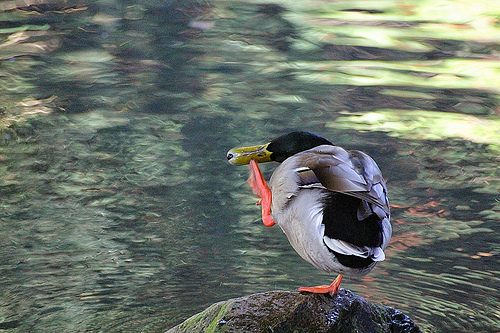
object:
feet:
[235, 164, 273, 221]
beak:
[228, 145, 278, 164]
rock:
[165, 289, 418, 332]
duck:
[211, 124, 487, 329]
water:
[63, 40, 256, 276]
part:
[186, 284, 253, 328]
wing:
[315, 226, 390, 253]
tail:
[309, 201, 420, 273]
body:
[40, 30, 344, 104]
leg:
[303, 270, 344, 301]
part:
[297, 286, 347, 294]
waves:
[142, 282, 228, 313]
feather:
[299, 165, 366, 196]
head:
[229, 130, 341, 168]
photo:
[30, 21, 465, 309]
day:
[287, 4, 476, 90]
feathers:
[327, 183, 395, 248]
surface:
[283, 306, 361, 327]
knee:
[257, 218, 286, 229]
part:
[111, 235, 206, 272]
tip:
[223, 152, 254, 176]